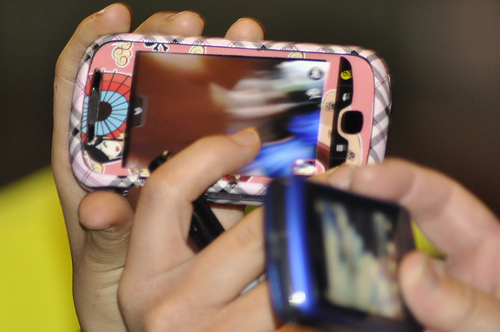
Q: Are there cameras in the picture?
A: Yes, there is a camera.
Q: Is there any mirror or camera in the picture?
A: Yes, there is a camera.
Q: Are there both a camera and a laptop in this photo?
A: No, there is a camera but no laptops.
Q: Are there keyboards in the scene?
A: No, there are no keyboards.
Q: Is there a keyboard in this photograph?
A: No, there are no keyboards.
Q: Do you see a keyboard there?
A: No, there are no keyboards.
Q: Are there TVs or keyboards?
A: No, there are no keyboards or tvs.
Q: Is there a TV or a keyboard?
A: No, there are no keyboards or televisions.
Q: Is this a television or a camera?
A: This is a camera.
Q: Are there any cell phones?
A: Yes, there is a cell phone.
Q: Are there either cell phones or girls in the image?
A: Yes, there is a cell phone.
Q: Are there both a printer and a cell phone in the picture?
A: No, there is a cell phone but no printers.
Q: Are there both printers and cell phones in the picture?
A: No, there is a cell phone but no printers.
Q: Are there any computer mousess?
A: No, there are no computer mousess.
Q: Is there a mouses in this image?
A: No, there are no computer mousess.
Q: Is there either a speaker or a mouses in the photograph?
A: No, there are no computer mousess or speakers.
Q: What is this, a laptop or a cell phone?
A: This is a cell phone.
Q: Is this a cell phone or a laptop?
A: This is a cell phone.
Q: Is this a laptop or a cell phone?
A: This is a cell phone.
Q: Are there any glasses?
A: No, there are no glasses.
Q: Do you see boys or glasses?
A: No, there are no glasses or boys.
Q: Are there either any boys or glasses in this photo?
A: No, there are no glasses or boys.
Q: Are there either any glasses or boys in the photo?
A: No, there are no glasses or boys.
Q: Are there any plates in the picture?
A: No, there are no plates.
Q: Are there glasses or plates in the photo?
A: No, there are no plates or glasses.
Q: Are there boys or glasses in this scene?
A: No, there are no glasses or boys.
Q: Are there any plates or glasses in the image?
A: No, there are no glasses or plates.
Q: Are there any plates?
A: No, there are no plates.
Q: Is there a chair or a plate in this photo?
A: No, there are no plates or chairs.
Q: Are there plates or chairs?
A: No, there are no plates or chairs.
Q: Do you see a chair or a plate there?
A: No, there are no plates or chairs.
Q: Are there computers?
A: No, there are no computers.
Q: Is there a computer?
A: No, there are no computers.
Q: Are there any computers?
A: No, there are no computers.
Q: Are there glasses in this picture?
A: No, there are no glasses.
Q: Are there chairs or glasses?
A: No, there are no glasses or chairs.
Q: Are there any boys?
A: No, there are no boys.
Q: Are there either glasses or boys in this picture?
A: No, there are no boys or glasses.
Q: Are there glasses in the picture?
A: No, there are no glasses.